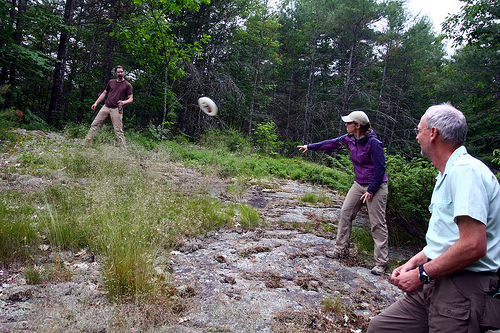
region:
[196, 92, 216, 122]
The frisbee is white.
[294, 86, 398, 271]
The lady throws a frisbee.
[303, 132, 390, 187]
The jacket is purple.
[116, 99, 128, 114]
The man has a bottle.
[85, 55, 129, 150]
The man waits for the frisbee.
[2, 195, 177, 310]
The grass is patchy.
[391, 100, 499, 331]
The man watches the frisbee.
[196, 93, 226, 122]
The frisbee flys in the air.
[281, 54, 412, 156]
The tree is missing leaves.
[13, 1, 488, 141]
There are alot of trees.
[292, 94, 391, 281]
the man's arm is stretched out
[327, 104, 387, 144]
the man is wearing a hat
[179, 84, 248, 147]
the frisbee is in the air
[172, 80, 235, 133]
the frisbee is white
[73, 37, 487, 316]
the people are standing in a forest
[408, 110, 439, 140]
the man is wearing glasses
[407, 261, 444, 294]
the man is wearing a watch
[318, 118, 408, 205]
the woman's jacket is purple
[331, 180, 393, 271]
the woman's pants are brown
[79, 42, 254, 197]
the man is going to catch the frisbee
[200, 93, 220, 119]
Frisbee in the air.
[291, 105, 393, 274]
Woman throwing the frisbee.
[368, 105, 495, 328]
Man watching the frisbee throwing.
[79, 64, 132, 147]
Man ready to catch frisbee.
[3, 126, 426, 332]
Rocky area in which they are standing.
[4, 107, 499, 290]
Shrubs and plants on the ground.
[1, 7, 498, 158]
Trees in the background.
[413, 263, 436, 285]
Man wearing a watch.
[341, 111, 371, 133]
Woman wearing a ball cap.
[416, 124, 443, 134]
Man wearing glasses.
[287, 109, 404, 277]
Person wearing a purple top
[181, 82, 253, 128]
Frisbee in the air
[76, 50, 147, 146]
Person wearing burgandy shirt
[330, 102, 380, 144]
Persons head with a baseball cap on it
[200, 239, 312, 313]
Rocky ground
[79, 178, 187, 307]
Grass growing on rocky ground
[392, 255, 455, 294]
Watch on a mans arm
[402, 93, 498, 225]
Man with grey hair and glasses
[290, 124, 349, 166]
Outstretched arm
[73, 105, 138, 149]
Tan colored pants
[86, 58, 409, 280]
two people playing frisbee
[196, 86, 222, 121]
white frisbee in flight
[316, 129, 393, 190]
puple jacket on woman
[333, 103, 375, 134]
cap on woman's head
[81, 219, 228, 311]
tall weeds on rocks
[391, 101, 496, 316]
man with gray hair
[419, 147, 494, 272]
short sleeved shirt on man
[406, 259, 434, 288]
watch on man's wrist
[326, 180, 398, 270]
tan pants on woman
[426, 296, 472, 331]
pocket on man's pants